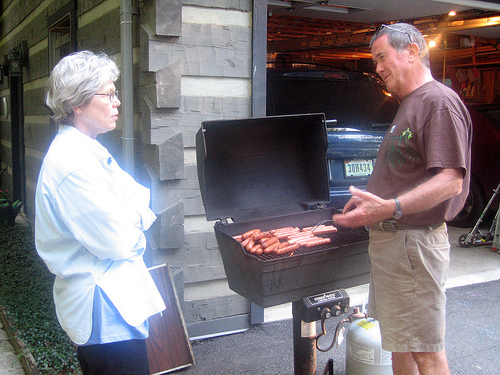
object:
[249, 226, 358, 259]
grill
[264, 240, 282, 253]
hotdogs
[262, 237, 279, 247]
hotdogs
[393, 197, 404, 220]
watch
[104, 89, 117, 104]
eyes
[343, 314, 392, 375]
propane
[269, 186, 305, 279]
row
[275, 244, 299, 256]
dogs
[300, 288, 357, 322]
knobs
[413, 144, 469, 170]
dark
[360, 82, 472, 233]
t shirt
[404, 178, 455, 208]
color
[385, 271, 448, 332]
color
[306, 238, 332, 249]
dogs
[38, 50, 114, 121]
hair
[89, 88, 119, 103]
glasses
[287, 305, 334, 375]
pole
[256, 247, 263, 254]
these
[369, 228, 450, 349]
shorts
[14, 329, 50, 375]
grass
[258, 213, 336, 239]
meat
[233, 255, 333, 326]
bbq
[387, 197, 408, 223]
wrist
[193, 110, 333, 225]
grill lid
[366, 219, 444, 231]
belt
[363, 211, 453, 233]
waist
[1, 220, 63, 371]
area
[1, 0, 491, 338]
building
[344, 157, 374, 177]
license plate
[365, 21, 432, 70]
hair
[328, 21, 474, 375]
man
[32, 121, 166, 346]
shirt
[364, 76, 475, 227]
shirt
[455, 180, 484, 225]
scooter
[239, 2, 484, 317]
garage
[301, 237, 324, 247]
hot dog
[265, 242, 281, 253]
hot dog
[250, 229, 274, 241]
hot dog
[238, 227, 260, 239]
hot dog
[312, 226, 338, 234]
hot dog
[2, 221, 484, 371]
ground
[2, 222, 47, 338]
plant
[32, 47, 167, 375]
lady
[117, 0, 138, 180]
rain gutter